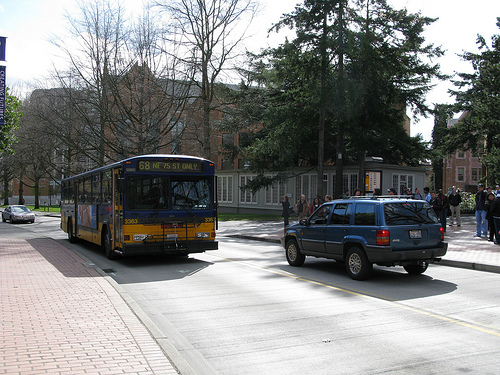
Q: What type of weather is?
A: It is sunny.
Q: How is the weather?
A: It is sunny.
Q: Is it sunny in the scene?
A: Yes, it is sunny.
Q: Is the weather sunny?
A: Yes, it is sunny.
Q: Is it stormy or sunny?
A: It is sunny.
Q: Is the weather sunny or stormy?
A: It is sunny.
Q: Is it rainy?
A: No, it is sunny.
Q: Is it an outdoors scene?
A: Yes, it is outdoors.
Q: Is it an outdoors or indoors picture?
A: It is outdoors.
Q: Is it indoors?
A: No, it is outdoors.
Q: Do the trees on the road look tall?
A: Yes, the trees are tall.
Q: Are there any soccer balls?
A: No, there are no soccer balls.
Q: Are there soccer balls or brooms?
A: No, there are no soccer balls or brooms.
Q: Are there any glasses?
A: No, there are no glasses.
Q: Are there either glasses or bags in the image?
A: No, there are no glasses or bags.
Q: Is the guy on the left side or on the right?
A: The guy is on the right of the image.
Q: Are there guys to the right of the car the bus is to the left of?
A: Yes, there is a guy to the right of the car.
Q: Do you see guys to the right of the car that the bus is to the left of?
A: Yes, there is a guy to the right of the car.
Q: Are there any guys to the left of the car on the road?
A: No, the guy is to the right of the car.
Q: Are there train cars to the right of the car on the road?
A: No, there is a guy to the right of the car.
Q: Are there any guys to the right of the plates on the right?
A: Yes, there is a guy to the right of the plates.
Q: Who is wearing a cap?
A: The guy is wearing a cap.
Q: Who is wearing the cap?
A: The guy is wearing a cap.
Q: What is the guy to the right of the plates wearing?
A: The guy is wearing a cap.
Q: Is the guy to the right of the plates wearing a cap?
A: Yes, the guy is wearing a cap.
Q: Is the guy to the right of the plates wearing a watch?
A: No, the guy is wearing a cap.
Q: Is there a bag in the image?
A: No, there are no bags.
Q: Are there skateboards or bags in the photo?
A: No, there are no bags or skateboards.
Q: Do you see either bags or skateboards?
A: No, there are no bags or skateboards.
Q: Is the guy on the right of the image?
A: Yes, the guy is on the right of the image.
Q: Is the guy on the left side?
A: No, the guy is on the right of the image.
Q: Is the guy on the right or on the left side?
A: The guy is on the right of the image.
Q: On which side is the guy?
A: The guy is on the right of the image.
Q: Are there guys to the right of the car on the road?
A: Yes, there is a guy to the right of the car.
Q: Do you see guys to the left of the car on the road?
A: No, the guy is to the right of the car.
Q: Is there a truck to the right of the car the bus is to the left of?
A: No, there is a guy to the right of the car.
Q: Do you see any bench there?
A: No, there are no benches.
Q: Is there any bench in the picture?
A: No, there are no benches.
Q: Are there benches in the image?
A: No, there are no benches.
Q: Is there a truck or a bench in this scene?
A: No, there are no benches or trucks.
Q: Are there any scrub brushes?
A: No, there are no scrub brushes.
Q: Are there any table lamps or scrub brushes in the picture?
A: No, there are no scrub brushes or table lamps.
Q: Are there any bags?
A: No, there are no bags.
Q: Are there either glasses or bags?
A: No, there are no bags or glasses.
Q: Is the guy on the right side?
A: Yes, the guy is on the right of the image.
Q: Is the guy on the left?
A: No, the guy is on the right of the image.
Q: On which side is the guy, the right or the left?
A: The guy is on the right of the image.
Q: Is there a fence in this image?
A: No, there are no fences.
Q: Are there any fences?
A: No, there are no fences.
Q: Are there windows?
A: Yes, there are windows.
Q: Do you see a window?
A: Yes, there are windows.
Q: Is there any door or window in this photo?
A: Yes, there are windows.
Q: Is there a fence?
A: No, there are no fences.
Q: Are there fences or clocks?
A: No, there are no fences or clocks.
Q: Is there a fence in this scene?
A: No, there are no fences.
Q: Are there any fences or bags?
A: No, there are no fences or bags.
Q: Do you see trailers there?
A: No, there are no trailers.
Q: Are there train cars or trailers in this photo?
A: No, there are no trailers or train cars.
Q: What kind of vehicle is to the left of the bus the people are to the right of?
A: The vehicle is a car.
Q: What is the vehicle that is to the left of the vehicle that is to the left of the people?
A: The vehicle is a car.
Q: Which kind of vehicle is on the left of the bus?
A: The vehicle is a car.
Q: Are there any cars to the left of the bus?
A: Yes, there is a car to the left of the bus.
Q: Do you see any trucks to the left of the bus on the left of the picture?
A: No, there is a car to the left of the bus.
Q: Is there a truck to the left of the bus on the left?
A: No, there is a car to the left of the bus.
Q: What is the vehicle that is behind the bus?
A: The vehicle is a car.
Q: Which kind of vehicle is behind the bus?
A: The vehicle is a car.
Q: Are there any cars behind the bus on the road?
A: Yes, there is a car behind the bus.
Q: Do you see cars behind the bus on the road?
A: Yes, there is a car behind the bus.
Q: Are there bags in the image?
A: No, there are no bags.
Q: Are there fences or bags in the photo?
A: No, there are no bags or fences.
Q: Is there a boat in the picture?
A: No, there are no boats.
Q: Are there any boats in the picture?
A: No, there are no boats.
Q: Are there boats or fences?
A: No, there are no boats or fences.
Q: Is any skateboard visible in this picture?
A: No, there are no skateboards.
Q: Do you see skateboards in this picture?
A: No, there are no skateboards.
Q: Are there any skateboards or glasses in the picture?
A: No, there are no skateboards or glasses.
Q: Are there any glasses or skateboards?
A: No, there are no skateboards or glasses.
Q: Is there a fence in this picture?
A: No, there are no fences.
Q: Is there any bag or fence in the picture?
A: No, there are no fences or bags.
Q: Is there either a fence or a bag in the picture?
A: No, there are no fences or bags.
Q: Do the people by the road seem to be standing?
A: Yes, the people are standing.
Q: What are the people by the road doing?
A: The people are standing.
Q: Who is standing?
A: The people are standing.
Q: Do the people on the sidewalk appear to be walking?
A: No, the people are standing.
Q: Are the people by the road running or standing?
A: The people are standing.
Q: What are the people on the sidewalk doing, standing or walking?
A: The people are standing.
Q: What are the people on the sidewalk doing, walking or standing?
A: The people are standing.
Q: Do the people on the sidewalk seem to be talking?
A: Yes, the people are talking.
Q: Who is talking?
A: The people are talking.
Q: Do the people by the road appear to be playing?
A: No, the people are talking.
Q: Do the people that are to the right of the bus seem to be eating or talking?
A: The people are talking.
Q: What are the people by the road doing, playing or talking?
A: The people are talking.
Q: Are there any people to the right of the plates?
A: No, the people are to the left of the plates.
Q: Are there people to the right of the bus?
A: Yes, there are people to the right of the bus.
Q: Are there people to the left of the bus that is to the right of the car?
A: No, the people are to the right of the bus.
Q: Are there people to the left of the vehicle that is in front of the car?
A: No, the people are to the right of the bus.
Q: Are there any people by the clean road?
A: Yes, there are people by the road.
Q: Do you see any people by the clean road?
A: Yes, there are people by the road.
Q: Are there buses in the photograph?
A: Yes, there is a bus.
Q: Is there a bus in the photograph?
A: Yes, there is a bus.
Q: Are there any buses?
A: Yes, there is a bus.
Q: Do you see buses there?
A: Yes, there is a bus.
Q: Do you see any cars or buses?
A: Yes, there is a bus.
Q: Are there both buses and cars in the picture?
A: Yes, there are both a bus and a car.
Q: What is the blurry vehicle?
A: The vehicle is a bus.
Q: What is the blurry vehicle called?
A: The vehicle is a bus.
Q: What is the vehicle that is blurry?
A: The vehicle is a bus.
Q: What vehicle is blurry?
A: The vehicle is a bus.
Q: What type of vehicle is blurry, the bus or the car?
A: The bus is blurry.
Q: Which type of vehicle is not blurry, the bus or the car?
A: The car is not blurry.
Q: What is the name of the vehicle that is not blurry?
A: The vehicle is a car.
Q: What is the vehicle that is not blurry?
A: The vehicle is a car.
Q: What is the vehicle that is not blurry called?
A: The vehicle is a car.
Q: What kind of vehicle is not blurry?
A: The vehicle is a car.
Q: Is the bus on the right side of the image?
A: No, the bus is on the left of the image.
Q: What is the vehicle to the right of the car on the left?
A: The vehicle is a bus.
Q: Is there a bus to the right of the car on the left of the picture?
A: Yes, there is a bus to the right of the car.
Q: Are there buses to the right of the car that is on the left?
A: Yes, there is a bus to the right of the car.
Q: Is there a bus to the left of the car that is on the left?
A: No, the bus is to the right of the car.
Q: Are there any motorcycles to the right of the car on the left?
A: No, there is a bus to the right of the car.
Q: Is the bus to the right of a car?
A: Yes, the bus is to the right of a car.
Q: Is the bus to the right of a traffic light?
A: No, the bus is to the right of a car.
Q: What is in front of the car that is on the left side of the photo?
A: The bus is in front of the car.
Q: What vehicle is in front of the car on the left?
A: The vehicle is a bus.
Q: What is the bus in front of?
A: The bus is in front of the car.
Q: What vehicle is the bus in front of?
A: The bus is in front of the car.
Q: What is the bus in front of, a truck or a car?
A: The bus is in front of a car.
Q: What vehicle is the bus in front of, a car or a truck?
A: The bus is in front of a car.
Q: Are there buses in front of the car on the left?
A: Yes, there is a bus in front of the car.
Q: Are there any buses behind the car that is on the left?
A: No, the bus is in front of the car.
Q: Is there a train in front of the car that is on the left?
A: No, there is a bus in front of the car.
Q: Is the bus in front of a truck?
A: No, the bus is in front of the car.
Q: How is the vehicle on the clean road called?
A: The vehicle is a bus.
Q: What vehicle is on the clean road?
A: The vehicle is a bus.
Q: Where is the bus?
A: The bus is on the road.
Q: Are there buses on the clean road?
A: Yes, there is a bus on the road.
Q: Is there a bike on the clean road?
A: No, there is a bus on the road.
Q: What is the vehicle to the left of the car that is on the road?
A: The vehicle is a bus.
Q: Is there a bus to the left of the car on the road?
A: Yes, there is a bus to the left of the car.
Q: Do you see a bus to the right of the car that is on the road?
A: No, the bus is to the left of the car.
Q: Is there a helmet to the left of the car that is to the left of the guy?
A: No, there is a bus to the left of the car.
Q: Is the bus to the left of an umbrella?
A: No, the bus is to the left of a car.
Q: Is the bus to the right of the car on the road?
A: No, the bus is to the left of the car.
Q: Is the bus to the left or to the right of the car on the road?
A: The bus is to the left of the car.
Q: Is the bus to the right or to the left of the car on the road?
A: The bus is to the left of the car.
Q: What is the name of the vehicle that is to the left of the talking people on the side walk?
A: The vehicle is a bus.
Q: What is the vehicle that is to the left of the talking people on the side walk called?
A: The vehicle is a bus.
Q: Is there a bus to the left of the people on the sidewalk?
A: Yes, there is a bus to the left of the people.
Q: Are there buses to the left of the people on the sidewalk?
A: Yes, there is a bus to the left of the people.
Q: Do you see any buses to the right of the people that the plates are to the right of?
A: No, the bus is to the left of the people.